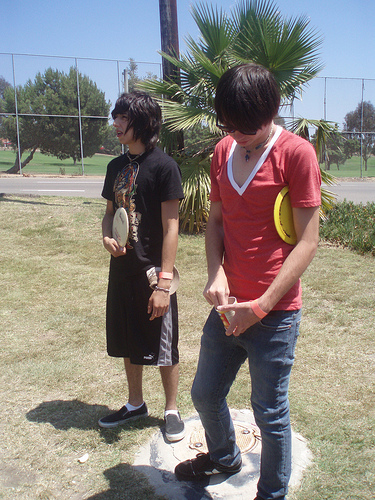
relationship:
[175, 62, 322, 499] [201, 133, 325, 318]
boys wearing shirt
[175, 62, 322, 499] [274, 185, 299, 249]
boys holding frisbee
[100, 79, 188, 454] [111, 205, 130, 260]
boy holding frisbee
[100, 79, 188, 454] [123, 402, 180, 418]
boy wearing socks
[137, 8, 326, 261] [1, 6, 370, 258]
tree in background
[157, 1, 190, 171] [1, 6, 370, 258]
pole in background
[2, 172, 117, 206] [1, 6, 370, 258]
road in background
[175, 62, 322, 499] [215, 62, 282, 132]
boys has hair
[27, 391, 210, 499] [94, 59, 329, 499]
shadows of boys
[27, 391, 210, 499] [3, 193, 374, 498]
shadows on ground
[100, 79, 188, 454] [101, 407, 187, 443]
boy wearing sneakers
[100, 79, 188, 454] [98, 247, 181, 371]
boy wearing shorts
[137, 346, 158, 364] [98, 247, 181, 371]
logo on shorts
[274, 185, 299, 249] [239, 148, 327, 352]
frisbee under arm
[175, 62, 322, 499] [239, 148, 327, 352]
boys has arm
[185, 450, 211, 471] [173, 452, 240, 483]
laces on shoe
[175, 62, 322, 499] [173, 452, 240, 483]
boys wearing shoe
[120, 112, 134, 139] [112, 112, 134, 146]
hair on face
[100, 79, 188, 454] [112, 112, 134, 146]
boy has face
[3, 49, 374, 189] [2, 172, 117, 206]
fence behind road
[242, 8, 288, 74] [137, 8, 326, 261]
frond on tree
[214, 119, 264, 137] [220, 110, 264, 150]
sunglasses on face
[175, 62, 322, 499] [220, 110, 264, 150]
boys has face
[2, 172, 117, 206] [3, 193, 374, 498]
road behind ground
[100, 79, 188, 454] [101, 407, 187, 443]
boy wearing shoes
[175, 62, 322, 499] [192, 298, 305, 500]
boys wearing jeans